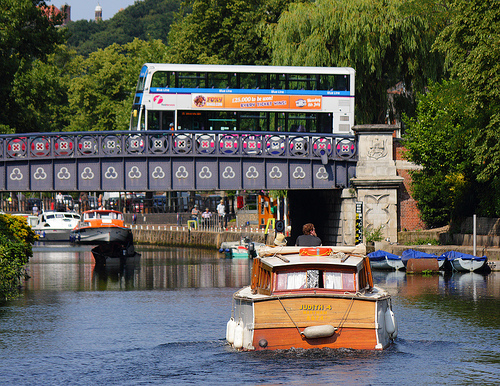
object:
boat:
[223, 241, 397, 353]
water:
[2, 274, 499, 385]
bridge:
[0, 127, 355, 197]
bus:
[126, 61, 356, 141]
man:
[293, 221, 324, 247]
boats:
[439, 249, 489, 274]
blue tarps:
[367, 248, 405, 273]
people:
[201, 208, 213, 228]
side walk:
[123, 222, 274, 238]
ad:
[195, 95, 322, 112]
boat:
[30, 210, 80, 243]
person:
[214, 197, 230, 231]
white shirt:
[216, 204, 226, 218]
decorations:
[7, 165, 25, 184]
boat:
[73, 205, 135, 246]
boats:
[218, 235, 256, 259]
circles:
[3, 134, 28, 160]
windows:
[276, 271, 306, 289]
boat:
[399, 247, 445, 276]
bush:
[0, 213, 40, 302]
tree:
[402, 20, 497, 234]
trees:
[85, 58, 187, 132]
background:
[1, 0, 497, 66]